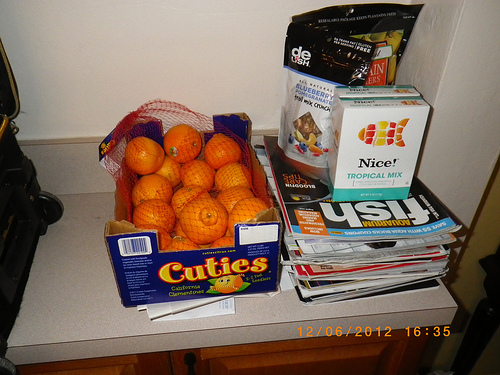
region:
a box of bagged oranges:
[103, 110, 278, 305]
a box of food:
[327, 97, 429, 202]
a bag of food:
[275, 18, 376, 178]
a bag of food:
[290, 3, 420, 88]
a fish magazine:
[257, 127, 460, 238]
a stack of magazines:
[253, 130, 461, 303]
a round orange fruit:
[175, 196, 226, 241]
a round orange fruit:
[131, 195, 171, 230]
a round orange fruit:
[225, 195, 263, 232]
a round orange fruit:
[166, 234, 200, 252]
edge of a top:
[241, 331, 250, 337]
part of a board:
[343, 356, 357, 368]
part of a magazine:
[314, 242, 348, 272]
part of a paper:
[188, 297, 210, 314]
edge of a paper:
[150, 308, 174, 319]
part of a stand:
[455, 325, 475, 356]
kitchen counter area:
[11, 3, 463, 321]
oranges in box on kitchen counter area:
[100, 112, 285, 305]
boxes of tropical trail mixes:
[323, 86, 431, 201]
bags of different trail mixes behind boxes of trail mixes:
[281, 2, 420, 179]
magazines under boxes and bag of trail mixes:
[257, 133, 464, 303]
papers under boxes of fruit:
[141, 295, 248, 322]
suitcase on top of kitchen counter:
[0, 127, 62, 372]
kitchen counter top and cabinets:
[9, 310, 454, 371]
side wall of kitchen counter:
[421, 127, 499, 263]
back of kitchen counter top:
[24, 141, 115, 195]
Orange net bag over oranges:
[100, 92, 267, 247]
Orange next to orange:
[177, 199, 231, 243]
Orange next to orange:
[131, 196, 173, 232]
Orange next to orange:
[164, 120, 202, 158]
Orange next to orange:
[122, 137, 166, 173]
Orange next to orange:
[204, 133, 239, 168]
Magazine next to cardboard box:
[260, 130, 455, 237]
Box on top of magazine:
[328, 98, 429, 205]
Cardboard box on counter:
[100, 109, 280, 306]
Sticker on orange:
[165, 143, 179, 160]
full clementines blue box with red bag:
[89, 99, 287, 306]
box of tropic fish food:
[323, 85, 433, 201]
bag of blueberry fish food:
[266, 18, 348, 177]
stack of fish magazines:
[289, 180, 468, 303]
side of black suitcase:
[9, 108, 81, 279]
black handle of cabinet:
[154, 328, 231, 374]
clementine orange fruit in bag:
[169, 190, 236, 245]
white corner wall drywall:
[437, 28, 496, 132]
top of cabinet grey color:
[42, 289, 107, 351]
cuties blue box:
[103, 220, 285, 291]